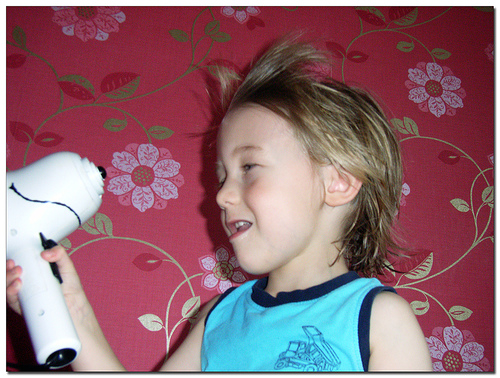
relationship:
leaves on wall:
[51, 66, 153, 105] [24, 18, 205, 150]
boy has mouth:
[42, 60, 436, 376] [206, 207, 260, 241]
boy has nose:
[42, 60, 436, 376] [209, 177, 242, 208]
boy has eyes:
[42, 60, 436, 376] [190, 155, 274, 183]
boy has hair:
[42, 60, 436, 376] [203, 35, 432, 267]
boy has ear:
[42, 60, 436, 376] [322, 151, 367, 211]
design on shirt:
[272, 319, 348, 371] [192, 262, 395, 372]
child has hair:
[165, 28, 425, 306] [206, 29, 412, 278]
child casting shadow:
[165, 28, 425, 306] [4, 296, 219, 375]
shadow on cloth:
[8, 313, 70, 376] [12, 37, 499, 373]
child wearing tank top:
[165, 28, 425, 306] [199, 268, 398, 376]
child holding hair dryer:
[165, 28, 425, 306] [4, 152, 106, 369]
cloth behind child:
[12, 37, 499, 373] [11, 32, 433, 370]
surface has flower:
[10, 8, 488, 375] [104, 140, 184, 210]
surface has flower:
[10, 8, 488, 375] [401, 58, 465, 121]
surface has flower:
[10, 8, 488, 375] [419, 322, 488, 375]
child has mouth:
[165, 28, 425, 306] [221, 215, 253, 240]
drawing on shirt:
[268, 324, 340, 373] [195, 268, 396, 376]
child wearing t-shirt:
[11, 32, 433, 370] [201, 269, 394, 374]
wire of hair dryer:
[8, 354, 63, 373] [10, 150, 119, 366]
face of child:
[194, 105, 322, 268] [146, 63, 435, 373]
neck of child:
[250, 242, 365, 301] [146, 63, 435, 373]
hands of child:
[3, 242, 93, 313] [146, 63, 435, 373]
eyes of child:
[190, 155, 274, 183] [146, 63, 435, 373]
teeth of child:
[230, 220, 247, 229] [146, 63, 435, 373]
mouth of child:
[206, 207, 260, 241] [158, 82, 441, 374]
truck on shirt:
[273, 325, 344, 369] [196, 273, 384, 366]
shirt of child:
[196, 273, 384, 366] [146, 63, 435, 373]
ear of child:
[321, 157, 370, 205] [146, 63, 435, 373]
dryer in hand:
[6, 144, 117, 366] [14, 247, 89, 328]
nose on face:
[209, 177, 242, 208] [215, 123, 270, 274]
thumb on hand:
[38, 243, 70, 268] [7, 242, 83, 310]